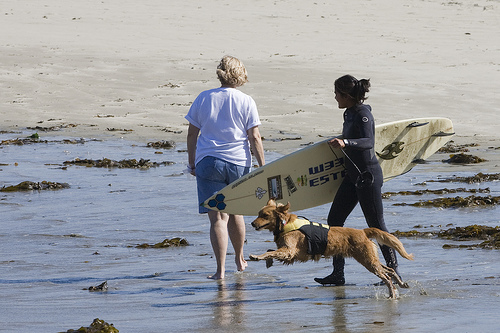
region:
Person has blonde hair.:
[213, 53, 255, 101]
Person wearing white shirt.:
[197, 90, 248, 153]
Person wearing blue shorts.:
[191, 165, 237, 200]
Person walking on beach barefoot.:
[199, 241, 254, 300]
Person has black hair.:
[335, 60, 379, 106]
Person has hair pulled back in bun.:
[331, 70, 381, 108]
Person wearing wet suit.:
[338, 108, 394, 238]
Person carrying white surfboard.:
[250, 111, 424, 227]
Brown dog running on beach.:
[238, 194, 438, 300]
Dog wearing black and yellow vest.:
[281, 198, 333, 273]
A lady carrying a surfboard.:
[328, 83, 385, 207]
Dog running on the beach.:
[249, 210, 429, 300]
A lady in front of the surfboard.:
[190, 48, 272, 213]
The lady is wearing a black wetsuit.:
[335, 67, 386, 221]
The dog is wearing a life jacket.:
[298, 212, 330, 262]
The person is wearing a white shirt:
[177, 90, 250, 151]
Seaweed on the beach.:
[27, 158, 143, 208]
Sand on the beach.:
[55, 10, 442, 119]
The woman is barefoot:
[188, 234, 257, 280]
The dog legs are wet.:
[355, 246, 419, 301]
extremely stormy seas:
[46, 50, 156, 122]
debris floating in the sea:
[83, 74, 185, 108]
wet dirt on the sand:
[35, 245, 122, 293]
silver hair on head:
[203, 46, 259, 81]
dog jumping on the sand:
[246, 198, 419, 298]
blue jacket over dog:
[280, 217, 340, 256]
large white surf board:
[210, 100, 459, 210]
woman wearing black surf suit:
[339, 109, 395, 241]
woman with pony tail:
[340, 79, 392, 96]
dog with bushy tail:
[356, 220, 426, 257]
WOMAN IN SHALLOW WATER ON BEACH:
[189, 44, 236, 281]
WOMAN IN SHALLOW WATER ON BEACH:
[327, 71, 403, 230]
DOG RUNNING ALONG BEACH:
[256, 196, 431, 305]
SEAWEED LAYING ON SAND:
[23, 162, 80, 202]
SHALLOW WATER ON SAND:
[36, 162, 375, 328]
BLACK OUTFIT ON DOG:
[277, 213, 342, 263]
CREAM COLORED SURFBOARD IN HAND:
[200, 109, 494, 209]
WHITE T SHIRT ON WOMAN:
[195, 86, 247, 156]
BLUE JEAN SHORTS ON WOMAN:
[187, 148, 254, 209]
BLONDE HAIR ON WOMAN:
[212, 55, 246, 77]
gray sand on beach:
[4, 3, 496, 128]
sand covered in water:
[4, 131, 492, 329]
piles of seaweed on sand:
[402, 172, 496, 244]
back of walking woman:
[185, 55, 264, 280]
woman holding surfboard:
[204, 76, 453, 225]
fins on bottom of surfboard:
[407, 121, 454, 166]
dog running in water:
[243, 201, 413, 296]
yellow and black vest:
[285, 218, 329, 256]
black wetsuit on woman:
[317, 108, 395, 285]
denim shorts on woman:
[196, 157, 248, 212]